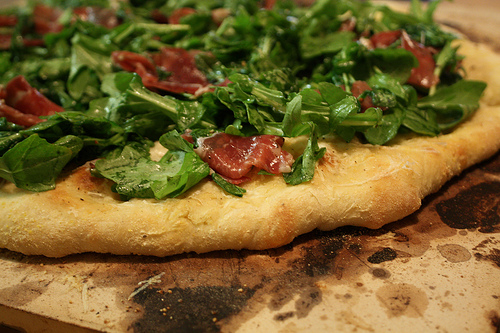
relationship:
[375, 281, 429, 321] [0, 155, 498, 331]
grease stain on table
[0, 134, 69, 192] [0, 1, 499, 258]
spinach on pizza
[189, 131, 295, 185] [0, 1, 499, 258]
meat on pizza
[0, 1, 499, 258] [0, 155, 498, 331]
pizza on table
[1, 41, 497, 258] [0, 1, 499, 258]
crust on pizza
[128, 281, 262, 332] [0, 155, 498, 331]
spot on table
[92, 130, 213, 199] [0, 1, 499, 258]
spinach on pizza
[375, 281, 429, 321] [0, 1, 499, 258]
grease stain from pizza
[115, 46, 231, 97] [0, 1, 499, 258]
meat on pizza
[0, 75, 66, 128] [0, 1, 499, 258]
meat on pizza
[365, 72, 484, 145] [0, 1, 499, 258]
spinach on pizza